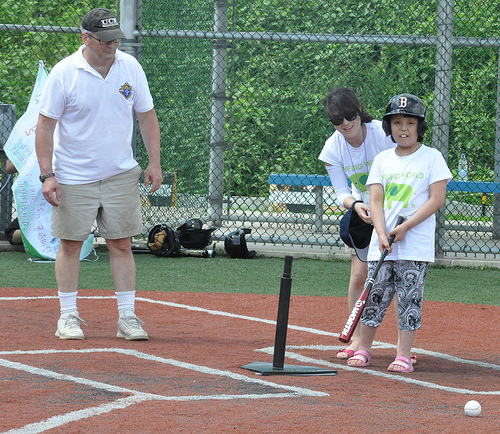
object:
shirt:
[38, 44, 155, 185]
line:
[118, 345, 329, 401]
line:
[1, 355, 162, 401]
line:
[0, 347, 115, 355]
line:
[1, 395, 150, 431]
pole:
[273, 255, 294, 371]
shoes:
[55, 311, 149, 341]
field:
[0, 243, 500, 434]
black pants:
[360, 260, 428, 332]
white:
[367, 263, 422, 295]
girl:
[318, 87, 419, 366]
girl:
[347, 93, 454, 373]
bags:
[2, 59, 100, 262]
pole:
[208, 0, 229, 227]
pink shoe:
[347, 350, 373, 367]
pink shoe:
[388, 355, 414, 373]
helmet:
[382, 93, 429, 143]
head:
[386, 92, 427, 147]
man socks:
[58, 290, 79, 316]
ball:
[464, 400, 482, 417]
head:
[80, 8, 118, 61]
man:
[35, 8, 162, 342]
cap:
[81, 8, 127, 42]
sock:
[115, 290, 136, 317]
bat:
[338, 213, 407, 343]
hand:
[379, 236, 393, 256]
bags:
[146, 218, 257, 259]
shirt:
[367, 143, 454, 263]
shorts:
[50, 165, 142, 242]